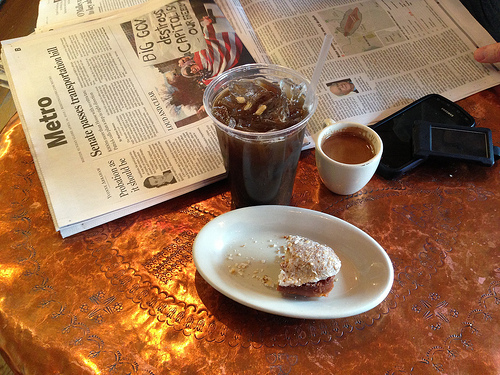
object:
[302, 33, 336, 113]
straw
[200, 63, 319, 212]
cup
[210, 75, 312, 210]
soda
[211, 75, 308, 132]
ice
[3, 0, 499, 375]
table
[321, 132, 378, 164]
coffe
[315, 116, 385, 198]
cup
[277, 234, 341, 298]
muffin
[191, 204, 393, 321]
plate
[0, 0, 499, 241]
newspaper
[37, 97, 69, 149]
metro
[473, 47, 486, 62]
fingernail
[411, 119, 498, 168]
case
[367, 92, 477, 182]
cellphone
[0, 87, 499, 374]
table cloth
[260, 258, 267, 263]
crumbs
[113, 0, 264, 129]
picture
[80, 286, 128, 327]
design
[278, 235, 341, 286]
top